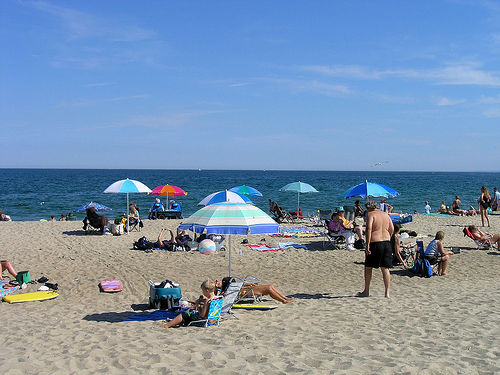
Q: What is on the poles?
A: Umbrellas.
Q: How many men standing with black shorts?
A: One.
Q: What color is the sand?
A: Tan.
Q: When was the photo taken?
A: Day time.